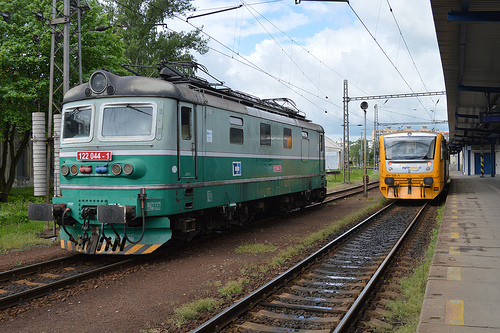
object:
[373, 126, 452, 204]
train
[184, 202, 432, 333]
track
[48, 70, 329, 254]
train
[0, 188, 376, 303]
track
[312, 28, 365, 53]
clouds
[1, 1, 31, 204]
tree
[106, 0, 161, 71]
tree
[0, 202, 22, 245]
grass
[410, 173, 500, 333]
platform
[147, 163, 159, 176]
aqua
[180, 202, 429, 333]
metal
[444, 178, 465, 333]
lines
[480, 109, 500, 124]
back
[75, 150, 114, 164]
plate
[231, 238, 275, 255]
patch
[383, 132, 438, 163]
front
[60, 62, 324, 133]
gray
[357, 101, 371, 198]
signal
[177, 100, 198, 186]
door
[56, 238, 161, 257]
stripes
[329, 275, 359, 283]
water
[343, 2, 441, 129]
wire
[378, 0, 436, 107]
wire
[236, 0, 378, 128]
wire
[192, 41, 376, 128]
wire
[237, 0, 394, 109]
wire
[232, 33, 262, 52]
sky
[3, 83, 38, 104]
leaves